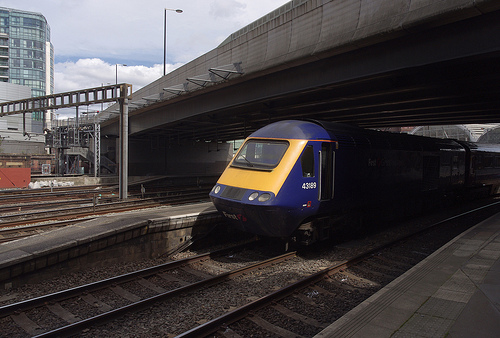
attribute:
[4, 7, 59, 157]
building — tall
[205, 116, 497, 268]
train — two-toned, blue, yellow, commuter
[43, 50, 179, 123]
clouds — white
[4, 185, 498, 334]
tracks — brown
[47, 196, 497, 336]
ballas — grey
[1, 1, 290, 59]
clouds — thick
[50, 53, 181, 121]
clouds — white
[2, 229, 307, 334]
tracks — train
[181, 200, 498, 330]
tracks — train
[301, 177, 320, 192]
numbers — white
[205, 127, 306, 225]
front — yellow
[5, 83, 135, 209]
frame — metal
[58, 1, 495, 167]
bridge — concrete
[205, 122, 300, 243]
front — yellow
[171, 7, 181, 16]
light — street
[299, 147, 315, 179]
window — side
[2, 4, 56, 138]
building — tall, glass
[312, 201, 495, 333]
platform — grey, concrete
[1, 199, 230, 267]
walkway — narrow, cement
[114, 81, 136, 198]
post — metal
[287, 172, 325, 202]
background — blue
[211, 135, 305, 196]
front — yellow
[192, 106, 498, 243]
train — blue, yellow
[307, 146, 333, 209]
handle bars — silver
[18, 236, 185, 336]
tracks — in front 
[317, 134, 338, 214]
door — side door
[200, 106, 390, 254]
train — yellow, blue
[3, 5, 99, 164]
building — blue